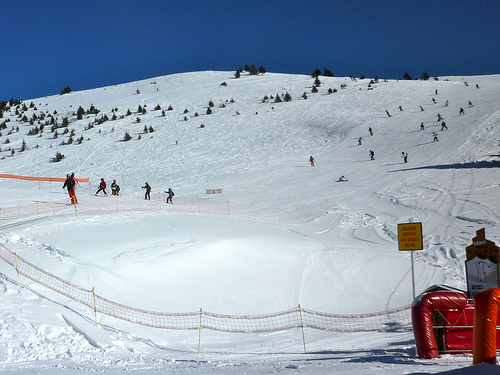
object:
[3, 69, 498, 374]
snow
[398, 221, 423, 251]
board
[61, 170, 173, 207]
group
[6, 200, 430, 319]
ice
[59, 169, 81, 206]
people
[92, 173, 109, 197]
people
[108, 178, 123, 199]
people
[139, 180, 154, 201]
people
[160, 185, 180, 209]
people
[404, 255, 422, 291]
pole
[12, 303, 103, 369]
few mark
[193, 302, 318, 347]
fence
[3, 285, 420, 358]
gate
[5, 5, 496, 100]
clouds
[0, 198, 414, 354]
fence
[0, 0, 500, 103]
sky